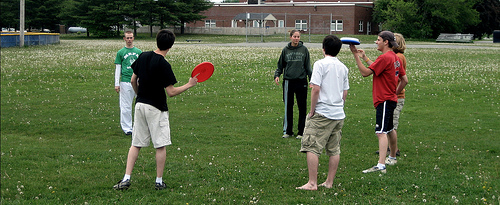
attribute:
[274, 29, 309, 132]
girl — black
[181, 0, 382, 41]
building — large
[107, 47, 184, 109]
shirt — black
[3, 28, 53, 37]
stripe — yellow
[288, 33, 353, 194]
boy — barefoot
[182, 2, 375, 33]
building — red, brick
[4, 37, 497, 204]
field — large, green, grass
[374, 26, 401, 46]
cap — black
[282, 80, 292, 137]
stripe — white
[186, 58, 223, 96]
frisbee — red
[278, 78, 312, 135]
pants — black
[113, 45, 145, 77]
shirt — green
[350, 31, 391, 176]
boy — white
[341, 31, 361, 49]
frisbee — blue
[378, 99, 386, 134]
stripe — white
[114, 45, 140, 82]
green shirt — short sleeved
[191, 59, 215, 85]
frisbee — red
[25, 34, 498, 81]
flowers — white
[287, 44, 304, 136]
clothes — green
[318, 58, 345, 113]
shirt — white